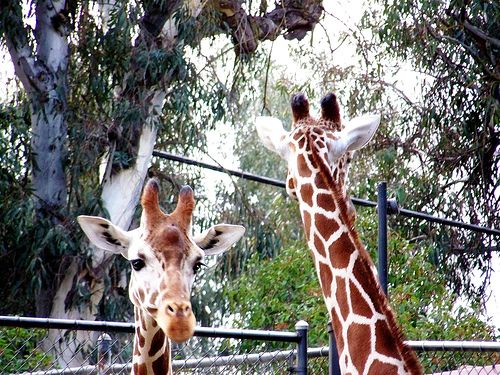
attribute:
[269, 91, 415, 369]
giraffe — standing, looking, taller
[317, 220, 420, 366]
neck — long, smooth, soft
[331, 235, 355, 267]
spot — brown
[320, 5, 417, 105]
sky — bright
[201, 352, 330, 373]
fencing — metal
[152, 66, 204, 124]
leaves — thin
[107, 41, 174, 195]
trunk — white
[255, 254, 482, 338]
bush — green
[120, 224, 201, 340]
face — calm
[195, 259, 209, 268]
eyelashes — long